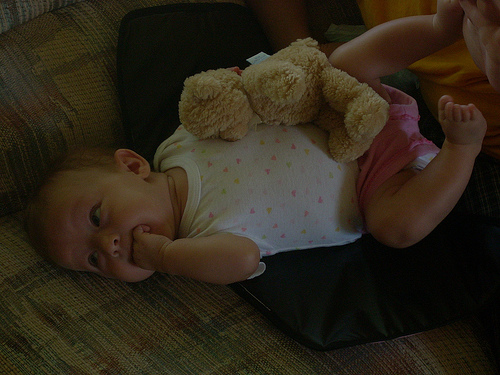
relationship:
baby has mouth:
[24, 3, 489, 287] [129, 221, 138, 276]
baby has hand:
[24, 3, 489, 287] [132, 223, 172, 271]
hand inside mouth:
[132, 223, 172, 271] [129, 221, 138, 276]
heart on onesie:
[263, 167, 271, 177] [152, 123, 362, 282]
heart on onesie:
[234, 157, 243, 166] [152, 123, 362, 282]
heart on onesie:
[316, 195, 325, 206] [152, 123, 362, 282]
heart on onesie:
[205, 159, 213, 168] [152, 123, 362, 282]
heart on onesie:
[290, 188, 298, 199] [152, 123, 362, 282]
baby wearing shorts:
[24, 3, 489, 287] [349, 78, 443, 205]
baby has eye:
[24, 3, 489, 287] [88, 200, 108, 229]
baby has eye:
[24, 3, 489, 287] [85, 248, 105, 272]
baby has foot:
[24, 3, 489, 287] [436, 93, 486, 156]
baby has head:
[24, 3, 489, 287] [22, 147, 176, 283]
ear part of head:
[114, 148, 152, 177] [22, 147, 176, 283]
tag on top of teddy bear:
[246, 50, 272, 65] [178, 37, 390, 162]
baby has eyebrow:
[24, 3, 489, 287] [68, 196, 83, 230]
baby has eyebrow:
[24, 3, 489, 287] [67, 245, 80, 272]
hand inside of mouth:
[132, 223, 172, 271] [129, 221, 138, 276]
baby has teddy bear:
[24, 3, 489, 287] [178, 37, 390, 162]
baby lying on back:
[24, 3, 489, 287] [181, 236, 378, 253]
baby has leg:
[24, 3, 489, 287] [327, 15, 435, 102]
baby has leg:
[24, 3, 489, 287] [362, 146, 479, 249]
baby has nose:
[24, 3, 489, 287] [88, 234, 123, 258]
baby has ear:
[24, 3, 489, 287] [114, 148, 152, 177]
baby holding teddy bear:
[24, 3, 489, 287] [178, 37, 390, 162]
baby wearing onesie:
[24, 3, 489, 287] [152, 123, 362, 282]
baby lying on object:
[24, 3, 489, 287] [116, 0, 273, 158]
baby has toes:
[24, 3, 489, 287] [437, 93, 481, 123]